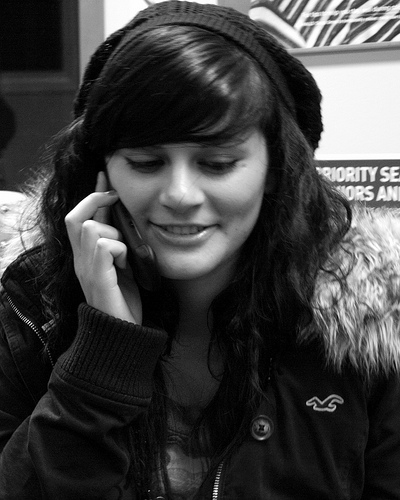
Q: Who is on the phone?
A: The girl.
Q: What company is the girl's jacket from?
A: Hollister.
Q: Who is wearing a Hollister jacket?
A: Girl talking on a cell phone.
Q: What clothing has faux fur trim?
A: The jacket.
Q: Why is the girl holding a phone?
A: She is talking on it.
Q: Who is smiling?
A: The girl on the phone.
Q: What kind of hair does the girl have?
A: Long hair.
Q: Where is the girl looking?
A: Down.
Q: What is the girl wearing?
A: A hat.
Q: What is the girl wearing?
A: A jacket.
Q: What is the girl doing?
A: Talking on a cell phone.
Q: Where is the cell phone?
A: In the woman's hand.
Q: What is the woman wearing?
A: Jacket.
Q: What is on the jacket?
A: Fur.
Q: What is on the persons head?
A: Black hat.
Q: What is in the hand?
A: A cellphone.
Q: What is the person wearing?
A: A coat.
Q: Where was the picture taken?
A: A subway.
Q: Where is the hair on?
A: The forehead.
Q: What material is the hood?
A: Fur.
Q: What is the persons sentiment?
A: Happiness.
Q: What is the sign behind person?
A: Priority sing.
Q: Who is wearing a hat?
A: A girl.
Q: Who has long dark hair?
A: A girl.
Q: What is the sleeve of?
A: A jacket.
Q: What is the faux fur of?
A: A jacket.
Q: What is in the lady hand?
A: Mobile.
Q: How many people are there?
A: 1.